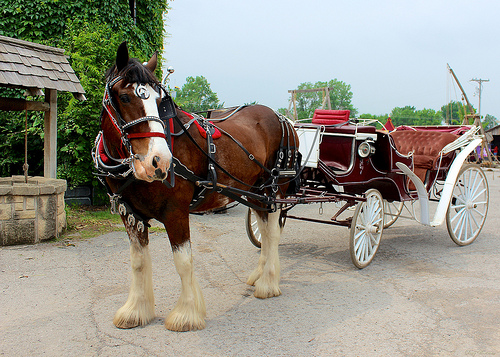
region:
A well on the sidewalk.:
[0, 28, 90, 248]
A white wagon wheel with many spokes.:
[346, 185, 392, 277]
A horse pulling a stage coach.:
[76, 35, 498, 340]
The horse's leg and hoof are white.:
[165, 242, 215, 337]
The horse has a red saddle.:
[180, 105, 232, 142]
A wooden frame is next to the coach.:
[283, 78, 340, 117]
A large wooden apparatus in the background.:
[436, 61, 498, 165]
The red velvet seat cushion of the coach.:
[388, 128, 450, 157]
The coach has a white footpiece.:
[391, 131, 487, 234]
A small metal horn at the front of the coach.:
[355, 141, 380, 161]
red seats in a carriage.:
[301, 101, 483, 210]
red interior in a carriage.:
[313, 103, 458, 185]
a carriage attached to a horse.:
[105, 81, 496, 251]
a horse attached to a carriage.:
[101, 78, 471, 256]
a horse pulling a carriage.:
[99, 74, 494, 244]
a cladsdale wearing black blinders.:
[89, 75, 196, 171]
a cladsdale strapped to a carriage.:
[96, 78, 424, 245]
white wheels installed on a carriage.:
[338, 155, 498, 246]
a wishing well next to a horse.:
[4, 67, 78, 279]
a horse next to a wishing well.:
[6, 73, 298, 307]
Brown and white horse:
[89, 38, 300, 336]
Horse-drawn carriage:
[247, 115, 491, 273]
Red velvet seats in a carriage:
[385, 125, 456, 190]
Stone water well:
[1, 33, 92, 245]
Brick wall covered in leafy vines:
[0, 0, 175, 206]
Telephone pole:
[469, 75, 488, 117]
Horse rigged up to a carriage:
[89, 39, 491, 334]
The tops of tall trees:
[163, 75, 488, 125]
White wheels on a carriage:
[350, 162, 490, 268]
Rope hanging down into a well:
[20, 100, 32, 182]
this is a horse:
[84, 24, 321, 331]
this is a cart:
[263, 35, 476, 270]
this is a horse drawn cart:
[78, 58, 499, 297]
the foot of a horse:
[248, 186, 303, 323]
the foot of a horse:
[169, 219, 217, 348]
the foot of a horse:
[110, 195, 159, 333]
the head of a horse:
[97, 33, 187, 187]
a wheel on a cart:
[334, 184, 404, 286]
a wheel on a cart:
[440, 150, 495, 259]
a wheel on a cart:
[241, 187, 301, 264]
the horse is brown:
[245, 116, 269, 147]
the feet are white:
[164, 293, 204, 332]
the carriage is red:
[331, 138, 352, 169]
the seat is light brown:
[413, 135, 430, 154]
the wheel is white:
[361, 211, 383, 245]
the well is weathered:
[2, 186, 47, 224]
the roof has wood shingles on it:
[11, 51, 48, 78]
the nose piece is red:
[129, 129, 165, 140]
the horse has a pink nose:
[143, 153, 168, 181]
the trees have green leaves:
[61, 6, 98, 46]